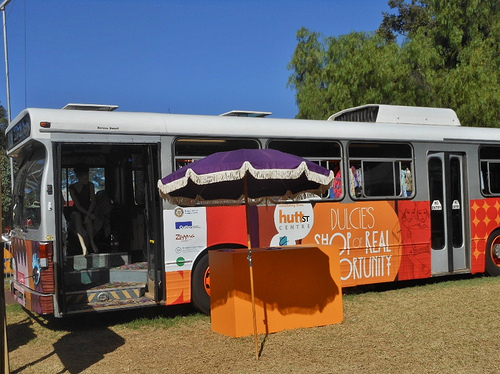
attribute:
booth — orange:
[205, 239, 360, 332]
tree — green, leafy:
[290, 0, 499, 125]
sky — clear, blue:
[69, 22, 163, 66]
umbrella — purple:
[155, 148, 332, 206]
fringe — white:
[156, 161, 332, 206]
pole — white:
[241, 171, 260, 358]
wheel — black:
[184, 255, 210, 316]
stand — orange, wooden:
[209, 244, 344, 336]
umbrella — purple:
[153, 154, 340, 358]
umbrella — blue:
[158, 149, 341, 196]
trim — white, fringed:
[155, 167, 333, 196]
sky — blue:
[25, 7, 283, 112]